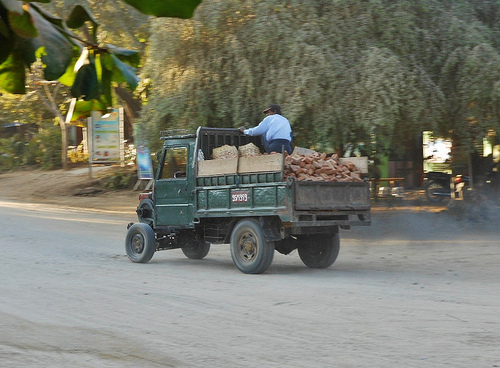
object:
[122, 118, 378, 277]
truck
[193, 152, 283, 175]
board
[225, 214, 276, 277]
wheel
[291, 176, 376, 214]
gate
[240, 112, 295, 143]
shirt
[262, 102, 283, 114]
hat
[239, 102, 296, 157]
man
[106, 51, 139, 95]
leaf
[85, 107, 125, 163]
sign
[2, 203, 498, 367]
road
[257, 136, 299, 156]
pants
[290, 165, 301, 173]
wood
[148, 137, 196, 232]
door